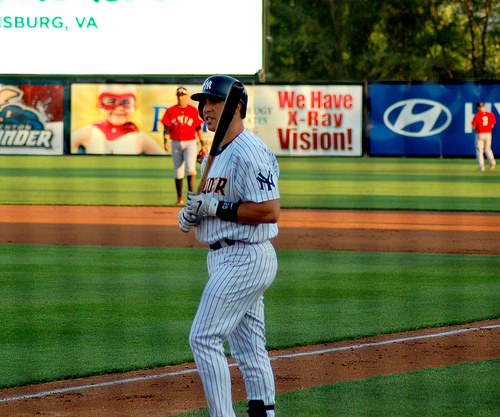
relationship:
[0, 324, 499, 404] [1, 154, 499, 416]
line on baseball field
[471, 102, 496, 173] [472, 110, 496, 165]
outfielder in a uniform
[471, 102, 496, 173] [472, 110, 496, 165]
outfielder in uniform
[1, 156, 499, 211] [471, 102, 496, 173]
grass under outfielder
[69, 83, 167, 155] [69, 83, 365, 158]
baby on banner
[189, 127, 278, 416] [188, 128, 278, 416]
uniform has blue stripes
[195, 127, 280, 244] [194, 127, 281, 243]
jersey has blue stripes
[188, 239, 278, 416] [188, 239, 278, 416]
pants have blue stripes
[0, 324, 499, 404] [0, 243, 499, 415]
line on infield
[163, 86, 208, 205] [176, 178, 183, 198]
man wearing a shin guard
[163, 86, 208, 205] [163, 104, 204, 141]
infielder wearing a jersey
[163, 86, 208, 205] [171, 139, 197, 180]
man wearing pants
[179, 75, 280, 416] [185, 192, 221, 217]
batter wearing a glove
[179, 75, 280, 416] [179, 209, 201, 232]
batter wearing a glove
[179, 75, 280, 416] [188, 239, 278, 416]
batter wearing pants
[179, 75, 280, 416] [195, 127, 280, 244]
batter wearing a jersey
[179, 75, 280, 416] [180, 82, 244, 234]
batter holding bat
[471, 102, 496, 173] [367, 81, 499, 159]
outfielder in front of banner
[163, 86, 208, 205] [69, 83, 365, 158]
man in front of banner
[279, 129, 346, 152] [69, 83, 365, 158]
vision on banner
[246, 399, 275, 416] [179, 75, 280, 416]
ankle support on batter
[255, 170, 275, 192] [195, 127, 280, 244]
new york yankee sign on jersey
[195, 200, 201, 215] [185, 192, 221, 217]
nike logo on glove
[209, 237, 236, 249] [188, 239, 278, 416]
belt on pants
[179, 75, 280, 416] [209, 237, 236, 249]
batter wearing a belt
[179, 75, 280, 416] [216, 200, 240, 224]
batter wearing a sweatband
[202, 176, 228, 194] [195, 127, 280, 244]
letters on jersey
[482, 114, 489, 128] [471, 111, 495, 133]
3 on jersey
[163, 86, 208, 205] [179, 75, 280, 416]
man facing batter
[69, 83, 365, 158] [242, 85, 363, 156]
banner partially white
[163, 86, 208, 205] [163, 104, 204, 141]
man wearing a jersey